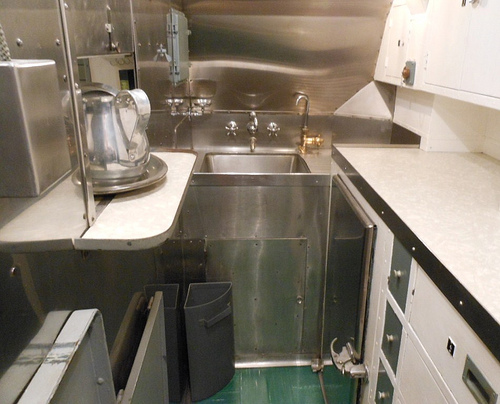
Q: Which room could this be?
A: It is a kitchen.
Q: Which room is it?
A: It is a kitchen.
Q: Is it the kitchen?
A: Yes, it is the kitchen.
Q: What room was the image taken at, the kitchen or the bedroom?
A: It was taken at the kitchen.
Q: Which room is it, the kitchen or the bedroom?
A: It is the kitchen.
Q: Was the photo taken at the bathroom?
A: No, the picture was taken in the kitchen.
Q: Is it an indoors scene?
A: Yes, it is indoors.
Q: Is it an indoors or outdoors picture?
A: It is indoors.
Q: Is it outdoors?
A: No, it is indoors.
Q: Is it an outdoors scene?
A: No, it is indoors.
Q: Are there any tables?
A: Yes, there is a table.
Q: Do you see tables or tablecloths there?
A: Yes, there is a table.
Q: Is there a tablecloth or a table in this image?
A: Yes, there is a table.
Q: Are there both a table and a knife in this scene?
A: No, there is a table but no knives.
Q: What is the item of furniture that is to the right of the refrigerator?
A: The piece of furniture is a table.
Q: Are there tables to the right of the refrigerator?
A: Yes, there is a table to the right of the refrigerator.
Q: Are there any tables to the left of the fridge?
A: No, the table is to the right of the fridge.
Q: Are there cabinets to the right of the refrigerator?
A: No, there is a table to the right of the refrigerator.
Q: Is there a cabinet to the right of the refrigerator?
A: No, there is a table to the right of the refrigerator.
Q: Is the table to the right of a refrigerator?
A: Yes, the table is to the right of a refrigerator.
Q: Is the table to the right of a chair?
A: No, the table is to the right of a refrigerator.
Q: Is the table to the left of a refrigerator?
A: No, the table is to the right of a refrigerator.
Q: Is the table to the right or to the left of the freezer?
A: The table is to the right of the freezer.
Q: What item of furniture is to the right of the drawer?
A: The piece of furniture is a table.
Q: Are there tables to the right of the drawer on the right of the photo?
A: Yes, there is a table to the right of the drawer.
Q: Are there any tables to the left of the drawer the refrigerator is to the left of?
A: No, the table is to the right of the drawer.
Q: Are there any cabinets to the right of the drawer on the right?
A: No, there is a table to the right of the drawer.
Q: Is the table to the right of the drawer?
A: Yes, the table is to the right of the drawer.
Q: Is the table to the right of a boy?
A: No, the table is to the right of the drawer.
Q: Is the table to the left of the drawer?
A: No, the table is to the right of the drawer.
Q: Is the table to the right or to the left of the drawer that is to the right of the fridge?
A: The table is to the right of the drawer.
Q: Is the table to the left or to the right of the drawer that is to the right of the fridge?
A: The table is to the right of the drawer.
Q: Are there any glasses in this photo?
A: No, there are no glasses.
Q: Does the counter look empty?
A: Yes, the counter is empty.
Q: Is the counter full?
A: No, the counter is empty.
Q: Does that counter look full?
A: No, the counter is empty.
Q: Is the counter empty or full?
A: The counter is empty.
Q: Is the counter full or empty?
A: The counter is empty.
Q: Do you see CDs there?
A: No, there are no cds.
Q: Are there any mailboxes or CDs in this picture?
A: No, there are no CDs or mailboxes.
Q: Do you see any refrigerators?
A: Yes, there is a refrigerator.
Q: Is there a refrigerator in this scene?
A: Yes, there is a refrigerator.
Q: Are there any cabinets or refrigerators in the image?
A: Yes, there is a refrigerator.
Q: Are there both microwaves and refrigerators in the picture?
A: No, there is a refrigerator but no microwaves.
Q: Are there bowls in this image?
A: No, there are no bowls.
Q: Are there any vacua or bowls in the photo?
A: No, there are no bowls or vacua.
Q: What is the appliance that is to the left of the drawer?
A: The appliance is a refrigerator.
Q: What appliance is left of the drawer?
A: The appliance is a refrigerator.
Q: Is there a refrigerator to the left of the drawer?
A: Yes, there is a refrigerator to the left of the drawer.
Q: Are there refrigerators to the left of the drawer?
A: Yes, there is a refrigerator to the left of the drawer.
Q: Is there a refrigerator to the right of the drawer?
A: No, the refrigerator is to the left of the drawer.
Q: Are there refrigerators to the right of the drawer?
A: No, the refrigerator is to the left of the drawer.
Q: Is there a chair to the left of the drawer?
A: No, there is a refrigerator to the left of the drawer.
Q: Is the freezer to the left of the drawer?
A: Yes, the freezer is to the left of the drawer.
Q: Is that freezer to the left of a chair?
A: No, the freezer is to the left of the drawer.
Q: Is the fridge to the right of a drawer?
A: No, the fridge is to the left of a drawer.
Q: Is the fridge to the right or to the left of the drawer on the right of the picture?
A: The fridge is to the left of the drawer.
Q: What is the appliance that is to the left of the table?
A: The appliance is a refrigerator.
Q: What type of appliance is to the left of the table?
A: The appliance is a refrigerator.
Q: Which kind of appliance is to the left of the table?
A: The appliance is a refrigerator.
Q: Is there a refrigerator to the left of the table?
A: Yes, there is a refrigerator to the left of the table.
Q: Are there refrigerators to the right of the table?
A: No, the refrigerator is to the left of the table.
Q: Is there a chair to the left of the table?
A: No, there is a refrigerator to the left of the table.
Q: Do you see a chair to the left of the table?
A: No, there is a refrigerator to the left of the table.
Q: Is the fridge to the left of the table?
A: Yes, the fridge is to the left of the table.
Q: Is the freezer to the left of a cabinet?
A: No, the freezer is to the left of the table.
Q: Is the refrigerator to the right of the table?
A: No, the refrigerator is to the left of the table.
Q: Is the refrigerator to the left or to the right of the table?
A: The refrigerator is to the left of the table.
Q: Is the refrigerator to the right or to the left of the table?
A: The refrigerator is to the left of the table.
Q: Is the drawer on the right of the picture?
A: Yes, the drawer is on the right of the image.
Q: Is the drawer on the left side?
A: No, the drawer is on the right of the image.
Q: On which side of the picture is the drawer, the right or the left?
A: The drawer is on the right of the image.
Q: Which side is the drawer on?
A: The drawer is on the right of the image.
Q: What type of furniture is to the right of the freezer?
A: The piece of furniture is a drawer.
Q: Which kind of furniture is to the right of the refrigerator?
A: The piece of furniture is a drawer.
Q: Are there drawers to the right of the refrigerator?
A: Yes, there is a drawer to the right of the refrigerator.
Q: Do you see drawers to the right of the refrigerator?
A: Yes, there is a drawer to the right of the refrigerator.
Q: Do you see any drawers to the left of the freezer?
A: No, the drawer is to the right of the freezer.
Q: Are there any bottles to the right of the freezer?
A: No, there is a drawer to the right of the freezer.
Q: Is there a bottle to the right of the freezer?
A: No, there is a drawer to the right of the freezer.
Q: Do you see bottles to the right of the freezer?
A: No, there is a drawer to the right of the freezer.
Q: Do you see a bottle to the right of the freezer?
A: No, there is a drawer to the right of the freezer.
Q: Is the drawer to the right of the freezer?
A: Yes, the drawer is to the right of the freezer.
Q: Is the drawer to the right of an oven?
A: No, the drawer is to the right of the freezer.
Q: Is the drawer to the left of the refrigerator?
A: No, the drawer is to the right of the refrigerator.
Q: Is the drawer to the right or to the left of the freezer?
A: The drawer is to the right of the freezer.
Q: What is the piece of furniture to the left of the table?
A: The piece of furniture is a drawer.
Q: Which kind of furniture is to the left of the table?
A: The piece of furniture is a drawer.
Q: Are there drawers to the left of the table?
A: Yes, there is a drawer to the left of the table.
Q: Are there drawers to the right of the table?
A: No, the drawer is to the left of the table.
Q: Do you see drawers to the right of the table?
A: No, the drawer is to the left of the table.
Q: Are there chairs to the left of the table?
A: No, there is a drawer to the left of the table.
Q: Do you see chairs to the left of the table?
A: No, there is a drawer to the left of the table.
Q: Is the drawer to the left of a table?
A: Yes, the drawer is to the left of a table.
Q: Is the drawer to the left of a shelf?
A: No, the drawer is to the left of a table.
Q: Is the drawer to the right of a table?
A: No, the drawer is to the left of a table.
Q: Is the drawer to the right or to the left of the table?
A: The drawer is to the left of the table.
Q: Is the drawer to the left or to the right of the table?
A: The drawer is to the left of the table.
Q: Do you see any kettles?
A: Yes, there is a kettle.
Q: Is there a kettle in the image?
A: Yes, there is a kettle.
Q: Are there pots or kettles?
A: Yes, there is a kettle.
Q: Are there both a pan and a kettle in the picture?
A: No, there is a kettle but no pans.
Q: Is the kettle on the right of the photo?
A: No, the kettle is on the left of the image.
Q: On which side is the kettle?
A: The kettle is on the left of the image.